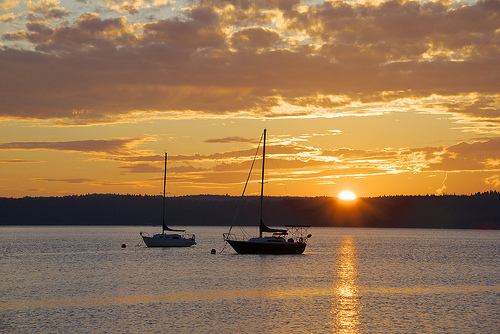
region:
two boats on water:
[98, 120, 395, 292]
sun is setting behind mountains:
[327, 175, 369, 230]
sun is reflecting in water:
[325, 174, 367, 322]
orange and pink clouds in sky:
[8, 4, 490, 212]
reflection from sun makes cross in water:
[22, 238, 486, 326]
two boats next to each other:
[115, 91, 399, 319]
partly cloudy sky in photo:
[27, 14, 498, 235]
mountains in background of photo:
[2, 167, 489, 231]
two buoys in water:
[115, 208, 246, 270]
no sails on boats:
[82, 121, 317, 233]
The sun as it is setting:
[307, 184, 385, 225]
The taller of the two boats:
[205, 121, 314, 265]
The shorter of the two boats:
[136, 147, 196, 247]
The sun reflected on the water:
[326, 233, 358, 333]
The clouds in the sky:
[0, 1, 498, 198]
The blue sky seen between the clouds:
[3, 0, 320, 49]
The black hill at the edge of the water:
[0, 187, 498, 236]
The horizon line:
[0, 188, 499, 200]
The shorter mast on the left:
[159, 149, 187, 233]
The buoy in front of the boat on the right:
[207, 243, 221, 257]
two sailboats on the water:
[113, 115, 323, 283]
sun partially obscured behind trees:
[301, 167, 391, 257]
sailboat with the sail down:
[207, 120, 307, 270]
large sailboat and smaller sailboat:
[126, 116, 321, 271]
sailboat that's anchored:
[115, 136, 200, 253]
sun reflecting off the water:
[315, 156, 475, 318]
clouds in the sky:
[35, 41, 475, 176]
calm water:
[311, 230, 466, 320]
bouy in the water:
[205, 237, 229, 260]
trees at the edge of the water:
[318, 176, 497, 237]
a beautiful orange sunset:
[316, 162, 382, 229]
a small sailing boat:
[203, 109, 323, 283]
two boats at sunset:
[13, 35, 462, 322]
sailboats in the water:
[7, 5, 487, 325]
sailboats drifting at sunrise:
[3, 6, 483, 324]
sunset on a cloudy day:
[6, 13, 493, 214]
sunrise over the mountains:
[2, 7, 494, 229]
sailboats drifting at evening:
[36, 100, 454, 301]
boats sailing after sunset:
[8, 104, 491, 301]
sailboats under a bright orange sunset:
[14, 12, 489, 304]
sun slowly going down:
[333, 183, 362, 205]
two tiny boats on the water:
[133, 123, 320, 269]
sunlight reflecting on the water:
[334, 223, 366, 333]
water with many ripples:
[28, 254, 441, 332]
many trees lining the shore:
[8, 192, 499, 229]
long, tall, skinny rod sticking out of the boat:
[254, 128, 271, 256]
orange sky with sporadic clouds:
[3, 130, 486, 195]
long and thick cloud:
[1, 26, 496, 124]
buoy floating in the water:
[209, 243, 218, 255]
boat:
[129, 151, 201, 260]